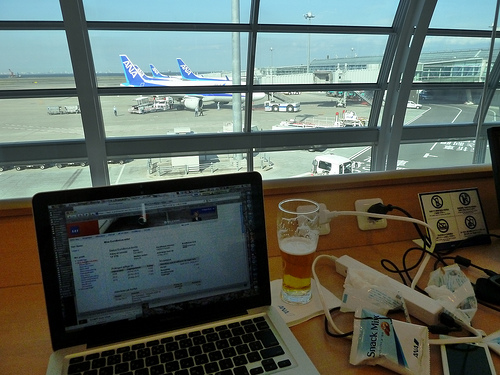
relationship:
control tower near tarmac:
[1, 0, 498, 373] [1, 74, 496, 197]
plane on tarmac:
[115, 51, 263, 105] [1, 74, 496, 197]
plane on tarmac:
[175, 57, 265, 101] [1, 74, 496, 197]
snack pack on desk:
[346, 308, 432, 374] [2, 160, 497, 373]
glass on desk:
[273, 193, 323, 307] [2, 160, 497, 373]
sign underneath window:
[416, 187, 494, 253] [1, 0, 499, 202]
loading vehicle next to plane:
[259, 98, 301, 115] [115, 51, 263, 105]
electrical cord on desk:
[367, 202, 456, 331] [2, 160, 497, 373]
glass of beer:
[273, 193, 323, 307] [279, 239, 315, 303]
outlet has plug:
[352, 193, 391, 232] [368, 202, 389, 221]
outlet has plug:
[298, 197, 334, 241] [316, 210, 334, 224]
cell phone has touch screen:
[435, 330, 496, 375] [445, 340, 490, 374]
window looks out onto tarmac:
[1, 0, 499, 202] [1, 74, 496, 197]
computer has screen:
[32, 171, 326, 375] [40, 179, 262, 340]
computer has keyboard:
[32, 171, 326, 375] [55, 309, 284, 372]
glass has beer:
[273, 193, 323, 307] [279, 239, 315, 303]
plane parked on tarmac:
[115, 51, 263, 105] [1, 74, 496, 197]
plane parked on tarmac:
[175, 57, 265, 101] [1, 74, 496, 197]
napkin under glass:
[263, 269, 342, 331] [273, 193, 323, 307]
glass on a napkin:
[273, 193, 323, 307] [263, 269, 342, 331]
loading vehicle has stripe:
[259, 98, 301, 115] [266, 104, 299, 111]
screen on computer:
[40, 179, 262, 340] [32, 171, 326, 375]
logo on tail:
[124, 61, 139, 82] [119, 51, 144, 93]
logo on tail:
[182, 63, 192, 76] [172, 53, 198, 84]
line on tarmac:
[425, 99, 464, 160] [1, 74, 496, 197]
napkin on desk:
[263, 269, 342, 331] [2, 160, 497, 373]